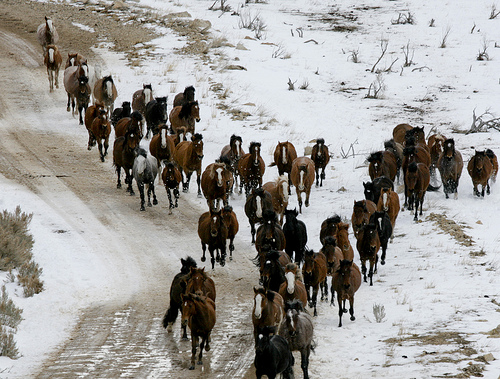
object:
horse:
[160, 254, 198, 332]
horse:
[179, 267, 217, 342]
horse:
[179, 293, 218, 373]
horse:
[277, 297, 315, 379]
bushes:
[0, 204, 46, 360]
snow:
[0, 0, 499, 377]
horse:
[319, 235, 344, 306]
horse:
[256, 245, 292, 285]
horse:
[300, 249, 328, 316]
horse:
[278, 260, 307, 315]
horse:
[485, 148, 498, 185]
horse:
[402, 158, 430, 221]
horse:
[362, 176, 395, 205]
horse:
[375, 187, 403, 244]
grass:
[0, 284, 25, 329]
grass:
[0, 326, 23, 360]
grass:
[15, 259, 46, 298]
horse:
[109, 100, 135, 128]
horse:
[115, 111, 143, 140]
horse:
[170, 125, 188, 147]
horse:
[172, 134, 206, 202]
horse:
[111, 129, 142, 197]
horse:
[218, 134, 247, 199]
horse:
[235, 139, 265, 197]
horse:
[310, 138, 333, 188]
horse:
[289, 155, 314, 215]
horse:
[199, 160, 235, 216]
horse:
[267, 139, 296, 196]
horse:
[159, 159, 185, 215]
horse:
[259, 174, 288, 227]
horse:
[243, 188, 276, 247]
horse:
[351, 198, 377, 237]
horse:
[319, 214, 340, 244]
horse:
[218, 203, 238, 262]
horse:
[196, 209, 227, 272]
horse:
[282, 206, 308, 269]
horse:
[252, 220, 286, 254]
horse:
[369, 210, 392, 266]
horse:
[356, 222, 382, 286]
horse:
[333, 221, 355, 268]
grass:
[0, 204, 37, 269]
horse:
[428, 133, 447, 185]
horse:
[366, 151, 400, 187]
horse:
[62, 51, 83, 69]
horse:
[60, 64, 88, 111]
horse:
[65, 74, 92, 125]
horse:
[172, 83, 195, 109]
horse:
[332, 258, 363, 329]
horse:
[35, 14, 61, 63]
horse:
[467, 149, 494, 198]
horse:
[149, 123, 176, 186]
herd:
[35, 15, 500, 379]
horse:
[41, 42, 65, 94]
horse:
[428, 131, 446, 147]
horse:
[390, 121, 416, 147]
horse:
[383, 137, 405, 185]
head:
[252, 284, 269, 320]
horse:
[168, 100, 203, 142]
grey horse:
[127, 147, 160, 211]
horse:
[252, 323, 296, 379]